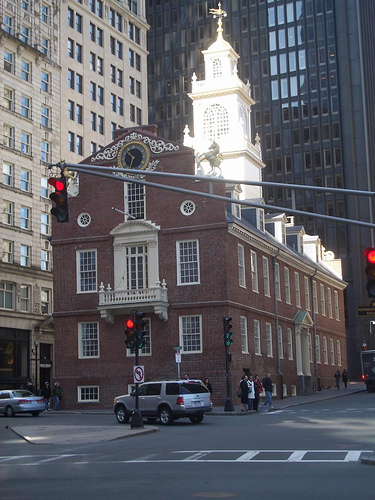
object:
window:
[77, 212, 92, 228]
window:
[180, 199, 196, 216]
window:
[126, 182, 145, 221]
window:
[126, 317, 152, 358]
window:
[179, 313, 204, 354]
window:
[139, 384, 161, 395]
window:
[125, 241, 148, 295]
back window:
[181, 384, 209, 393]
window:
[281, 102, 290, 122]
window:
[238, 244, 246, 289]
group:
[262, 372, 275, 408]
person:
[236, 374, 249, 412]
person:
[246, 374, 255, 411]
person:
[253, 374, 263, 412]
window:
[78, 320, 100, 359]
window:
[271, 80, 280, 100]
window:
[279, 53, 286, 74]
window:
[128, 48, 134, 68]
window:
[20, 131, 30, 153]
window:
[251, 250, 259, 292]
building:
[146, 0, 374, 381]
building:
[0, 0, 149, 408]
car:
[0, 387, 47, 417]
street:
[1, 392, 373, 497]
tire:
[160, 408, 175, 426]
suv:
[112, 377, 214, 426]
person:
[261, 373, 274, 409]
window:
[176, 237, 201, 287]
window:
[77, 248, 98, 294]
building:
[47, 136, 348, 417]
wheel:
[115, 406, 127, 422]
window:
[166, 383, 179, 395]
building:
[180, 2, 263, 199]